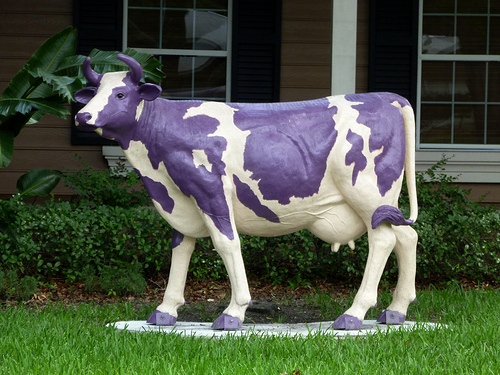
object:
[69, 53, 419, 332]
statue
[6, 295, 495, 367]
grass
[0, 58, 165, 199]
bushes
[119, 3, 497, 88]
window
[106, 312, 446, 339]
platform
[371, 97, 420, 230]
tail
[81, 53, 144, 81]
horns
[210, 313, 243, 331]
hoof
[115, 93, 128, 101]
eye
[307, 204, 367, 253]
white udders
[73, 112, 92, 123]
nose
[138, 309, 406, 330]
four hooves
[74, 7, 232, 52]
shutters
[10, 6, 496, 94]
house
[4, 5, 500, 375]
garden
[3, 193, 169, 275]
hedge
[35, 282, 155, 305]
wood chips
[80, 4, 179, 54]
siding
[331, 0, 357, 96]
pole